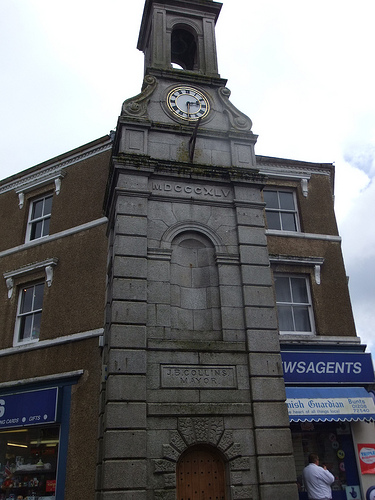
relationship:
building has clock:
[0, 3, 372, 498] [163, 83, 212, 125]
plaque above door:
[160, 364, 239, 389] [175, 442, 235, 498]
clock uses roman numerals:
[163, 83, 212, 125] [186, 87, 193, 96]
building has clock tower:
[0, 3, 372, 498] [116, 2, 259, 157]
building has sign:
[0, 3, 372, 498] [160, 364, 239, 389]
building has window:
[0, 3, 372, 498] [273, 266, 317, 337]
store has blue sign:
[280, 347, 374, 500] [284, 348, 374, 385]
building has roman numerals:
[0, 3, 372, 498] [186, 87, 193, 96]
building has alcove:
[0, 3, 372, 498] [162, 226, 218, 341]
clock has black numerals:
[163, 83, 212, 125] [181, 87, 191, 95]